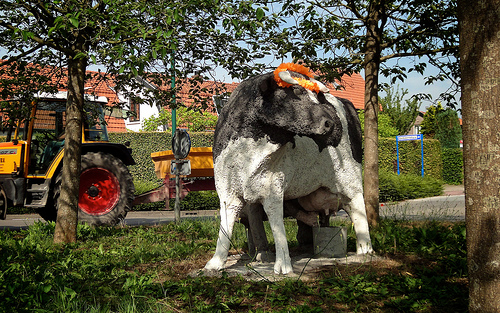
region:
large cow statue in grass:
[202, 41, 333, 253]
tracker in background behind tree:
[5, 79, 144, 225]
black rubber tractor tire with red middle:
[55, 156, 145, 231]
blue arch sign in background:
[380, 118, 431, 188]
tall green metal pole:
[162, 29, 181, 138]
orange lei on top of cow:
[270, 50, 319, 88]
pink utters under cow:
[288, 189, 348, 216]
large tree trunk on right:
[439, 3, 498, 278]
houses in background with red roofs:
[12, 59, 347, 148]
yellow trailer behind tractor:
[141, 138, 252, 195]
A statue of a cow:
[175, 72, 393, 287]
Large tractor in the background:
[5, 95, 138, 227]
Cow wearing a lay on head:
[273, 58, 331, 97]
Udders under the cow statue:
[295, 175, 351, 219]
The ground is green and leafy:
[22, 248, 139, 305]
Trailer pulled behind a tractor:
[138, 140, 223, 192]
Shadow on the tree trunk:
[462, 199, 498, 306]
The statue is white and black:
[181, 59, 410, 296]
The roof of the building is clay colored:
[75, 65, 217, 117]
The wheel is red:
[70, 167, 144, 237]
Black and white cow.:
[236, 63, 395, 282]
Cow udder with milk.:
[293, 175, 363, 277]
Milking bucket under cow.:
[296, 197, 358, 289]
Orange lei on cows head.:
[257, 44, 330, 108]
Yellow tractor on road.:
[12, 77, 164, 254]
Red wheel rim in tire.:
[73, 145, 146, 259]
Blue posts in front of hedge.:
[389, 126, 442, 193]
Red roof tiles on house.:
[342, 75, 379, 114]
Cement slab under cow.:
[188, 231, 445, 302]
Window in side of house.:
[122, 92, 157, 141]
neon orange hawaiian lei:
[272, 62, 321, 97]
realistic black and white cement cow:
[203, 67, 376, 276]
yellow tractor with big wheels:
[0, 87, 137, 230]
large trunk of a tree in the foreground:
[455, 0, 495, 310]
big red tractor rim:
[76, 166, 117, 214]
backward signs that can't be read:
[170, 126, 191, 221]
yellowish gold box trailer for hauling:
[147, 143, 212, 178]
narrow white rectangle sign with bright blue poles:
[391, 131, 424, 176]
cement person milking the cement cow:
[285, 198, 321, 228]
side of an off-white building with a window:
[114, 72, 166, 131]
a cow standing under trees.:
[182, 66, 382, 278]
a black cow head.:
[227, 68, 342, 153]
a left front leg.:
[258, 178, 313, 290]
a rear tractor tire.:
[60, 146, 152, 239]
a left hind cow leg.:
[318, 150, 387, 258]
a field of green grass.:
[0, 222, 478, 302]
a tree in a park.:
[453, 0, 498, 307]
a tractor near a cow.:
[0, 86, 165, 252]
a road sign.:
[158, 125, 198, 212]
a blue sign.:
[383, 126, 433, 190]